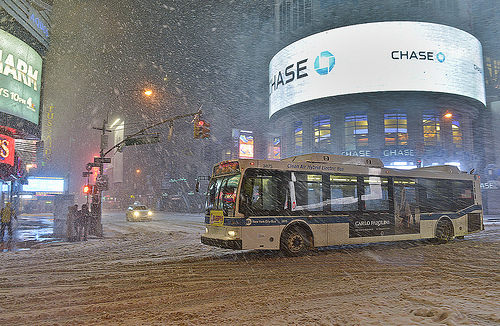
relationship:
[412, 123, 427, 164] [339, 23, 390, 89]
building has sign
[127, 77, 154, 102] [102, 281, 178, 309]
light of streets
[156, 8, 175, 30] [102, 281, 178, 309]
snow on streets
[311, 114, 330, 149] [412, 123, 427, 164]
windows on building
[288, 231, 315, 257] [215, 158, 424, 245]
tire of bus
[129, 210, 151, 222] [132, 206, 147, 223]
headlight on car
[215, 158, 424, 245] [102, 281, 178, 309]
bus on streets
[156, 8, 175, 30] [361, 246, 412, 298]
snow on ground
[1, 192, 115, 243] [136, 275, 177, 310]
people on road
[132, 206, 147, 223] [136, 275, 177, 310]
car on road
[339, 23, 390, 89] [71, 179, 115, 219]
sign on pole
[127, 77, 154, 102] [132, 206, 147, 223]
light on car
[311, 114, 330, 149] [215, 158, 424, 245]
windows of bus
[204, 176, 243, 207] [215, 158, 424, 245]
windshield of bus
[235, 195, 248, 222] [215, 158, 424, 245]
mirror of bus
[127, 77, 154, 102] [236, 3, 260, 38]
light of city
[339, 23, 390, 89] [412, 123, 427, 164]
sign on building